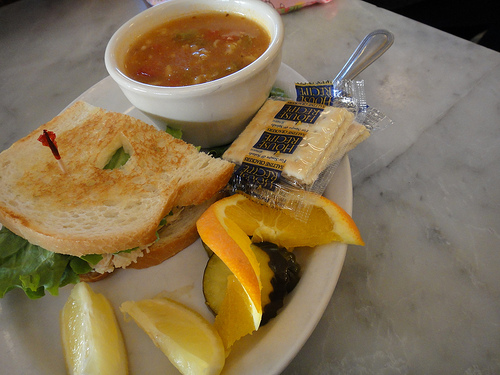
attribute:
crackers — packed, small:
[217, 70, 397, 225]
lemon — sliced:
[49, 282, 226, 372]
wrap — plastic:
[205, 146, 352, 217]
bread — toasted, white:
[15, 103, 225, 251]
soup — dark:
[121, 9, 270, 87]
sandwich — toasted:
[0, 98, 235, 298]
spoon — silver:
[270, 19, 444, 147]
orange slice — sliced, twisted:
[193, 185, 365, 355]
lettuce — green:
[2, 225, 104, 298]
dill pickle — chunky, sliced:
[248, 245, 295, 310]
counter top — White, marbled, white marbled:
[2, 3, 499, 373]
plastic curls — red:
[38, 125, 58, 152]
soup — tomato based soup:
[123, 8, 270, 79]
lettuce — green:
[1, 234, 86, 301]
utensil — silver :
[330, 23, 398, 97]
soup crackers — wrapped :
[223, 95, 377, 178]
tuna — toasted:
[93, 245, 151, 265]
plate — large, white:
[2, 44, 366, 373]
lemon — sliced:
[119, 288, 233, 369]